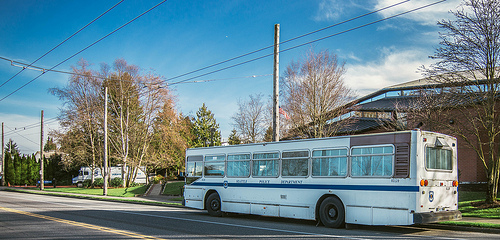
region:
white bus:
[188, 116, 466, 236]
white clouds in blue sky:
[375, 21, 393, 38]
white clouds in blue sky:
[340, 26, 380, 60]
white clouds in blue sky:
[235, 22, 256, 44]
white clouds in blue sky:
[361, 5, 398, 59]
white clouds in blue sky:
[191, 42, 221, 62]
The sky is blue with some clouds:
[313, 7, 446, 89]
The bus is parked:
[151, 140, 372, 220]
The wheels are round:
[301, 185, 370, 232]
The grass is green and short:
[461, 188, 491, 220]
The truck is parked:
[66, 160, 151, 192]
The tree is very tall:
[193, 101, 228, 161]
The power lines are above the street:
[0, 108, 99, 158]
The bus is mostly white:
[225, 155, 305, 229]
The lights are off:
[418, 170, 436, 205]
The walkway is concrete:
[142, 177, 174, 204]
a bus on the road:
[168, 61, 475, 200]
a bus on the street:
[225, 103, 472, 228]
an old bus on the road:
[179, 125, 436, 233]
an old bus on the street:
[153, 134, 460, 236]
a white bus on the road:
[172, 104, 382, 239]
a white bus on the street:
[165, 117, 356, 220]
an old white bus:
[167, 115, 388, 231]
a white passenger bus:
[185, 127, 462, 227]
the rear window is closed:
[421, 146, 451, 173]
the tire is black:
[313, 196, 346, 224]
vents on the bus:
[393, 140, 411, 180]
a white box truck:
[75, 164, 147, 185]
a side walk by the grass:
[144, 178, 168, 195]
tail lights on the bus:
[418, 179, 430, 186]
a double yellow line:
[0, 208, 154, 238]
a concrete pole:
[272, 24, 278, 139]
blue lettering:
[229, 178, 304, 185]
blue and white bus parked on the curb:
[168, 123, 480, 233]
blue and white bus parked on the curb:
[169, 133, 469, 234]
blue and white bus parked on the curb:
[157, 139, 478, 211]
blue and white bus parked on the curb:
[183, 125, 466, 237]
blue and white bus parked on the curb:
[165, 124, 483, 238]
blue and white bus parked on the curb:
[168, 115, 471, 234]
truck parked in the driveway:
[65, 155, 152, 185]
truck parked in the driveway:
[62, 156, 151, 189]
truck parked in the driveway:
[71, 155, 149, 188]